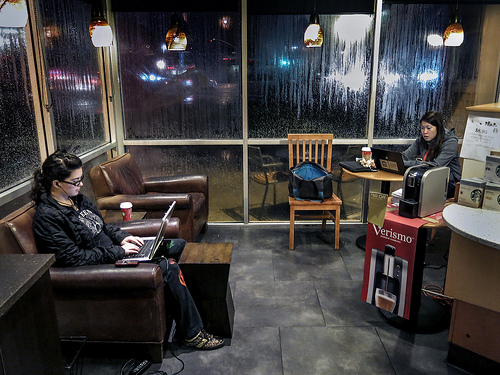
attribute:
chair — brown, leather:
[84, 145, 213, 231]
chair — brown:
[284, 123, 344, 256]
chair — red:
[94, 156, 211, 222]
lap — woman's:
[104, 233, 184, 268]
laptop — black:
[372, 144, 411, 177]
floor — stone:
[200, 213, 373, 354]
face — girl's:
[48, 160, 88, 197]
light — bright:
[80, 19, 117, 50]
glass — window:
[381, 14, 444, 132]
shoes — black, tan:
[180, 331, 228, 348]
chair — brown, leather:
[96, 151, 211, 234]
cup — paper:
[118, 198, 138, 221]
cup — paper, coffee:
[362, 145, 371, 165]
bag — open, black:
[288, 160, 340, 203]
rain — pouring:
[4, 25, 417, 151]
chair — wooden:
[287, 134, 343, 254]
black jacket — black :
[19, 190, 159, 266]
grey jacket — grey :
[397, 123, 465, 185]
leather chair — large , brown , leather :
[1, 185, 191, 370]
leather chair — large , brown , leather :
[66, 144, 215, 248]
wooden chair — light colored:
[278, 123, 348, 259]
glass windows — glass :
[14, 10, 469, 220]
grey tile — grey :
[74, 210, 466, 371]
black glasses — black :
[49, 169, 88, 190]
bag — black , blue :
[285, 158, 340, 199]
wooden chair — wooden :
[283, 128, 348, 256]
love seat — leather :
[90, 142, 226, 247]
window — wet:
[262, 46, 370, 125]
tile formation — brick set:
[243, 245, 368, 373]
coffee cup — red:
[355, 134, 384, 174]